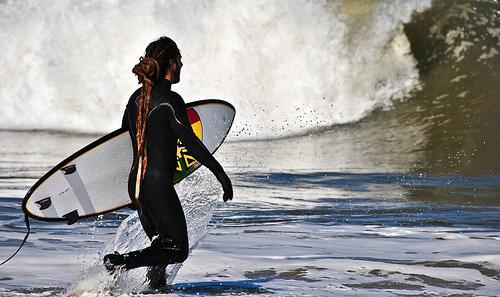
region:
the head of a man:
[124, 35, 212, 94]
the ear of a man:
[160, 53, 183, 80]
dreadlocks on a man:
[127, 37, 194, 218]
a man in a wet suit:
[89, 17, 224, 256]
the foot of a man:
[101, 241, 151, 286]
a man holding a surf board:
[15, 23, 282, 231]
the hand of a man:
[211, 147, 271, 214]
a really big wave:
[69, 19, 494, 162]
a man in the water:
[85, 60, 341, 279]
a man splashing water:
[89, 62, 391, 287]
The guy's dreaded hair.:
[131, 56, 151, 176]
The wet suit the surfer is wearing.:
[123, 75, 203, 283]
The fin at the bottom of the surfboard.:
[35, 200, 53, 212]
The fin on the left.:
[60, 164, 78, 176]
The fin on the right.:
[58, 212, 82, 224]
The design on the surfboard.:
[172, 110, 204, 175]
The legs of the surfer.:
[133, 203, 193, 294]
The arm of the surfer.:
[172, 93, 217, 180]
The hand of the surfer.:
[217, 177, 235, 202]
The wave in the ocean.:
[10, 2, 498, 123]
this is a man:
[93, 26, 243, 292]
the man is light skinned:
[170, 68, 176, 83]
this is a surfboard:
[83, 138, 136, 204]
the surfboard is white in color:
[88, 152, 109, 205]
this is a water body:
[318, 145, 435, 295]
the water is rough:
[263, 19, 340, 99]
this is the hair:
[143, 42, 160, 75]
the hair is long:
[140, 83, 141, 146]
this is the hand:
[182, 103, 220, 180]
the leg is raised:
[96, 222, 163, 274]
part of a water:
[268, 195, 313, 252]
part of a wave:
[333, 190, 365, 223]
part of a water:
[377, 145, 426, 224]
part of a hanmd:
[180, 160, 212, 216]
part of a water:
[354, 243, 377, 280]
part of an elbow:
[183, 132, 218, 187]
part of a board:
[203, 109, 222, 141]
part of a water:
[323, 223, 355, 261]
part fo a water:
[314, 173, 348, 210]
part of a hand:
[221, 173, 262, 208]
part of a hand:
[203, 155, 258, 260]